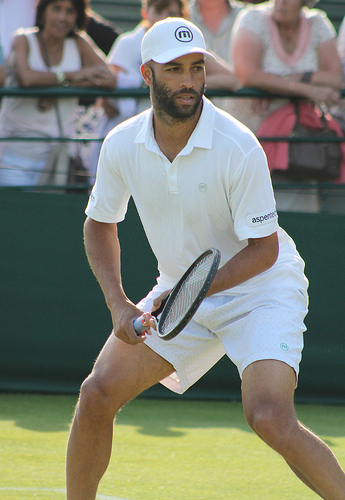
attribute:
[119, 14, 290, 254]
man — playing, scruffy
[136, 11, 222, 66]
hat — white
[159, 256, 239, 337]
racket — black, playing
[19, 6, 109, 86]
woman — watching, looking, dark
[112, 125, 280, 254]
shirt — white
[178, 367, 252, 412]
shorts — white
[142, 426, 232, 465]
court — green, sunny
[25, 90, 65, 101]
rail — green